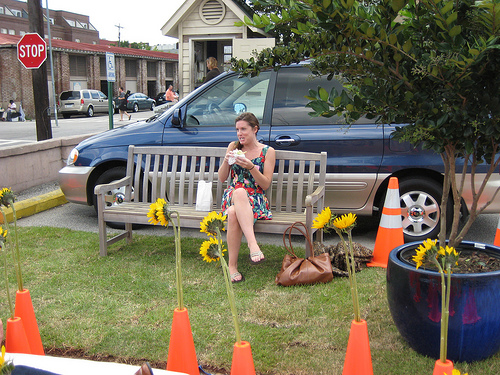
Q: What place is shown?
A: It is a lawn.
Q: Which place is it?
A: It is a lawn.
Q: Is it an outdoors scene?
A: Yes, it is outdoors.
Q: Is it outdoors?
A: Yes, it is outdoors.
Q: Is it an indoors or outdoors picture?
A: It is outdoors.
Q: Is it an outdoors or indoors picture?
A: It is outdoors.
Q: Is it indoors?
A: No, it is outdoors.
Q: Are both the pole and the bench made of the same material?
A: Yes, both the pole and the bench are made of wood.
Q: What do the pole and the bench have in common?
A: The material, both the pole and the bench are wooden.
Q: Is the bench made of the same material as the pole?
A: Yes, both the bench and the pole are made of wood.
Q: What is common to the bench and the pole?
A: The material, both the bench and the pole are wooden.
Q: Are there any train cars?
A: No, there are no train cars.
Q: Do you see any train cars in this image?
A: No, there are no train cars.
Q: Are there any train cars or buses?
A: No, there are no train cars or buses.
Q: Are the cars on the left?
A: Yes, the cars are on the left of the image.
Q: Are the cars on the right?
A: No, the cars are on the left of the image.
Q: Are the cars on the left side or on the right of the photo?
A: The cars are on the left of the image.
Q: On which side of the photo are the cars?
A: The cars are on the left of the image.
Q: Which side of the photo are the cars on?
A: The cars are on the left of the image.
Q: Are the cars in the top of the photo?
A: Yes, the cars are in the top of the image.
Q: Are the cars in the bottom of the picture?
A: No, the cars are in the top of the image.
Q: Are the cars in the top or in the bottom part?
A: The cars are in the top of the image.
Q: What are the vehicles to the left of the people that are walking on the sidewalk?
A: The vehicles are cars.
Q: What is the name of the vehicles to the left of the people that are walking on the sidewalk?
A: The vehicles are cars.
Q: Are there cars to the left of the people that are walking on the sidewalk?
A: Yes, there are cars to the left of the people.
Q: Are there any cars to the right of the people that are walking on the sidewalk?
A: No, the cars are to the left of the people.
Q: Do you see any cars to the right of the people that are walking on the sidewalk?
A: No, the cars are to the left of the people.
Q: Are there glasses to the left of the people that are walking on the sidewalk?
A: No, there are cars to the left of the people.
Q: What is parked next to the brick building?
A: The cars are parked next to the building.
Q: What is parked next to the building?
A: The cars are parked next to the building.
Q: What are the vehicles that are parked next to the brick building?
A: The vehicles are cars.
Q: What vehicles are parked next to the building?
A: The vehicles are cars.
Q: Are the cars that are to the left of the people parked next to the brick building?
A: Yes, the cars are parked next to the building.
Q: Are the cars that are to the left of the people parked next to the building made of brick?
A: Yes, the cars are parked next to the building.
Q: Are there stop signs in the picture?
A: Yes, there is a stop sign.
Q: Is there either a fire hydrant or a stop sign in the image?
A: Yes, there is a stop sign.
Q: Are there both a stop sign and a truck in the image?
A: No, there is a stop sign but no trucks.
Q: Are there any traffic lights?
A: No, there are no traffic lights.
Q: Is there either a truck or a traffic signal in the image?
A: No, there are no traffic lights or trucks.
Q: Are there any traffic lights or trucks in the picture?
A: No, there are no traffic lights or trucks.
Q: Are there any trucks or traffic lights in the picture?
A: No, there are no traffic lights or trucks.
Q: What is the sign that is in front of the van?
A: The sign is a stop sign.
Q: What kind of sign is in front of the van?
A: The sign is a stop sign.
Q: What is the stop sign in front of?
A: The stop sign is in front of the van.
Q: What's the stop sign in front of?
A: The stop sign is in front of the van.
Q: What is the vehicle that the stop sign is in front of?
A: The vehicle is a van.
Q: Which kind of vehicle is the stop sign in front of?
A: The stop sign is in front of the van.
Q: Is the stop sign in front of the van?
A: Yes, the stop sign is in front of the van.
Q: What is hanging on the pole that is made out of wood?
A: The stop sign is hanging on the pole.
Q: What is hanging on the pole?
A: The stop sign is hanging on the pole.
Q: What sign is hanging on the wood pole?
A: The sign is a stop sign.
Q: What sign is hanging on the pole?
A: The sign is a stop sign.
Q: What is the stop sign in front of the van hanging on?
A: The stop sign is hanging on the pole.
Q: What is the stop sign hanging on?
A: The stop sign is hanging on the pole.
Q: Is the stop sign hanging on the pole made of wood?
A: Yes, the stop sign is hanging on the pole.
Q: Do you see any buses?
A: No, there are no buses.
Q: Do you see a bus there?
A: No, there are no buses.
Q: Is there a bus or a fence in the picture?
A: No, there are no buses or fences.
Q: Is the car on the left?
A: Yes, the car is on the left of the image.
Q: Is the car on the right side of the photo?
A: No, the car is on the left of the image.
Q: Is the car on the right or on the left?
A: The car is on the left of the image.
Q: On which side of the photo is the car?
A: The car is on the left of the image.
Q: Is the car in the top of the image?
A: Yes, the car is in the top of the image.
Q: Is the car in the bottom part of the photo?
A: No, the car is in the top of the image.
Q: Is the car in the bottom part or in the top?
A: The car is in the top of the image.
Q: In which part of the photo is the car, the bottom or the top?
A: The car is in the top of the image.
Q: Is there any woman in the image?
A: Yes, there is a woman.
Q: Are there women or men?
A: Yes, there is a woman.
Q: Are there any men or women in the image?
A: Yes, there is a woman.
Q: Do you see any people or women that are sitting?
A: Yes, the woman is sitting.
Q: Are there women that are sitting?
A: Yes, there is a woman that is sitting.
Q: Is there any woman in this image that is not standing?
A: Yes, there is a woman that is sitting.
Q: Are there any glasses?
A: No, there are no glasses.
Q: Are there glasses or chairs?
A: No, there are no glasses or chairs.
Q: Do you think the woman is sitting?
A: Yes, the woman is sitting.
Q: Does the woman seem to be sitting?
A: Yes, the woman is sitting.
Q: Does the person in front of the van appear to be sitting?
A: Yes, the woman is sitting.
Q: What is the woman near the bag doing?
A: The woman is sitting.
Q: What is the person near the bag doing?
A: The woman is sitting.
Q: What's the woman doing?
A: The woman is sitting.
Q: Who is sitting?
A: The woman is sitting.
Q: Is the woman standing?
A: No, the woman is sitting.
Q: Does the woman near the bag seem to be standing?
A: No, the woman is sitting.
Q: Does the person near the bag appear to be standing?
A: No, the woman is sitting.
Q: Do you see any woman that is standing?
A: No, there is a woman but she is sitting.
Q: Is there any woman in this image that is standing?
A: No, there is a woman but she is sitting.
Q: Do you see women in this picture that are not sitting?
A: No, there is a woman but she is sitting.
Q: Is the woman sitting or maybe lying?
A: The woman is sitting.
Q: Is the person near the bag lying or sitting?
A: The woman is sitting.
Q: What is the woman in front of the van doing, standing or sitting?
A: The woman is sitting.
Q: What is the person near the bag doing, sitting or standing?
A: The woman is sitting.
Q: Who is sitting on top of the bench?
A: The woman is sitting on top of the bench.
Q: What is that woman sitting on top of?
A: The woman is sitting on top of the bench.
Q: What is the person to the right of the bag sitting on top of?
A: The woman is sitting on top of the bench.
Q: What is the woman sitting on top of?
A: The woman is sitting on top of the bench.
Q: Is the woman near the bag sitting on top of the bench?
A: Yes, the woman is sitting on top of the bench.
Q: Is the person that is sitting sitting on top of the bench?
A: Yes, the woman is sitting on top of the bench.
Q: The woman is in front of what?
A: The woman is in front of the van.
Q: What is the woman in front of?
A: The woman is in front of the van.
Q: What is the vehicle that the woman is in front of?
A: The vehicle is a van.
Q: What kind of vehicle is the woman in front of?
A: The woman is in front of the van.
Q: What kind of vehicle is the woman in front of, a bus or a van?
A: The woman is in front of a van.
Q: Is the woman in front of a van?
A: Yes, the woman is in front of a van.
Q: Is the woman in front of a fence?
A: No, the woman is in front of a van.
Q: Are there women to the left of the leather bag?
A: Yes, there is a woman to the left of the bag.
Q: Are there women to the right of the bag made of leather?
A: No, the woman is to the left of the bag.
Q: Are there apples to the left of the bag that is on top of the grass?
A: No, there is a woman to the left of the bag.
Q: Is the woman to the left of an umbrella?
A: No, the woman is to the left of a bag.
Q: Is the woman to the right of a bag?
A: No, the woman is to the left of a bag.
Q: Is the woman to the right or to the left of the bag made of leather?
A: The woman is to the left of the bag.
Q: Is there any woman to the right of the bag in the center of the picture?
A: Yes, there is a woman to the right of the bag.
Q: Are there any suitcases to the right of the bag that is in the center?
A: No, there is a woman to the right of the bag.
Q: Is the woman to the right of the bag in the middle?
A: Yes, the woman is to the right of the bag.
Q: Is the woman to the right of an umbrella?
A: No, the woman is to the right of the bag.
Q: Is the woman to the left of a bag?
A: No, the woman is to the right of a bag.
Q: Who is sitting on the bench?
A: The woman is sitting on the bench.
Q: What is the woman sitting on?
A: The woman is sitting on the bench.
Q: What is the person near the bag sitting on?
A: The woman is sitting on the bench.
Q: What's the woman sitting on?
A: The woman is sitting on the bench.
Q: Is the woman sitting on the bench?
A: Yes, the woman is sitting on the bench.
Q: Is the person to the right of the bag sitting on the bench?
A: Yes, the woman is sitting on the bench.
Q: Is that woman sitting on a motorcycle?
A: No, the woman is sitting on the bench.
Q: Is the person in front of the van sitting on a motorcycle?
A: No, the woman is sitting on the bench.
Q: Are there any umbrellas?
A: No, there are no umbrellas.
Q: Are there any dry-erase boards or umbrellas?
A: No, there are no umbrellas or dry-erase boards.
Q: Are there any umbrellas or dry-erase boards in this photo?
A: No, there are no umbrellas or dry-erase boards.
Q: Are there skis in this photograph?
A: No, there are no skis.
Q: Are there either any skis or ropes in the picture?
A: No, there are no skis or ropes.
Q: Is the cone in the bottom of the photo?
A: Yes, the cone is in the bottom of the image.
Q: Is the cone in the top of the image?
A: No, the cone is in the bottom of the image.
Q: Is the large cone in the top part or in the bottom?
A: The traffic cone is in the bottom of the image.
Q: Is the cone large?
A: Yes, the cone is large.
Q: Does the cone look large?
A: Yes, the cone is large.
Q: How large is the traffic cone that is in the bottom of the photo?
A: The traffic cone is large.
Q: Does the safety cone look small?
A: No, the safety cone is large.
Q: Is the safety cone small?
A: No, the safety cone is large.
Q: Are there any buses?
A: No, there are no buses.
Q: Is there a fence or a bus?
A: No, there are no buses or fences.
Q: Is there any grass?
A: Yes, there is grass.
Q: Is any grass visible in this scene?
A: Yes, there is grass.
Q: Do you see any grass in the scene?
A: Yes, there is grass.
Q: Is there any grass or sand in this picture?
A: Yes, there is grass.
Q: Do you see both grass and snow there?
A: No, there is grass but no snow.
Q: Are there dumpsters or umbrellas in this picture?
A: No, there are no umbrellas or dumpsters.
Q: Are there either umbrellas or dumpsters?
A: No, there are no umbrellas or dumpsters.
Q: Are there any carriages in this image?
A: No, there are no carriages.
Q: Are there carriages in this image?
A: No, there are no carriages.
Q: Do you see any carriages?
A: No, there are no carriages.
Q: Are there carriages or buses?
A: No, there are no carriages or buses.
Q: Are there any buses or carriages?
A: No, there are no carriages or buses.